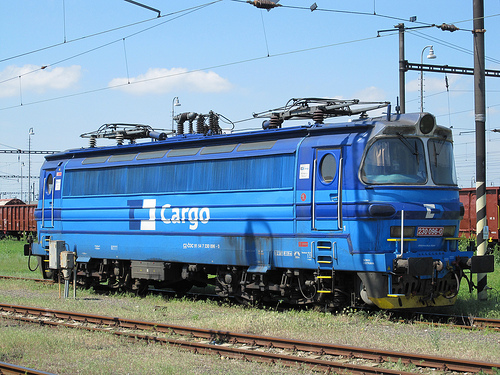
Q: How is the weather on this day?
A: It is clear.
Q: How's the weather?
A: It is clear.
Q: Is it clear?
A: Yes, it is clear.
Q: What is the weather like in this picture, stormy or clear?
A: It is clear.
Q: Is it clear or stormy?
A: It is clear.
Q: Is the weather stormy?
A: No, it is clear.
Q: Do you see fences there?
A: No, there are no fences.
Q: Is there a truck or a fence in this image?
A: No, there are no fences or trucks.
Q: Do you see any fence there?
A: No, there are no fences.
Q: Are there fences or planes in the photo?
A: No, there are no fences or planes.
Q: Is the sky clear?
A: Yes, the sky is clear.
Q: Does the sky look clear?
A: Yes, the sky is clear.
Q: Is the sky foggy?
A: No, the sky is clear.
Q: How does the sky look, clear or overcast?
A: The sky is clear.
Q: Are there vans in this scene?
A: No, there are no vans.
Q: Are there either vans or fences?
A: No, there are no vans or fences.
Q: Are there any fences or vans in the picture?
A: No, there are no vans or fences.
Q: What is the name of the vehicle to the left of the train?
A: The vehicle is a car.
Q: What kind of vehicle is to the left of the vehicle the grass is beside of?
A: The vehicle is a car.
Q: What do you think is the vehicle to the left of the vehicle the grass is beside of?
A: The vehicle is a car.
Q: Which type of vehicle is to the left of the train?
A: The vehicle is a car.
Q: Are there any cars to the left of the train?
A: Yes, there is a car to the left of the train.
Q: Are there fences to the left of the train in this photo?
A: No, there is a car to the left of the train.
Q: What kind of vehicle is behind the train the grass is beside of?
A: The vehicle is a car.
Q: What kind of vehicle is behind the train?
A: The vehicle is a car.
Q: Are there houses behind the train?
A: No, there is a car behind the train.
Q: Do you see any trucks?
A: No, there are no trucks.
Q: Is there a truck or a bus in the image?
A: No, there are no trucks or buses.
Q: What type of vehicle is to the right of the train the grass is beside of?
A: The vehicle is a car.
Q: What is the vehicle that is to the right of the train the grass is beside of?
A: The vehicle is a car.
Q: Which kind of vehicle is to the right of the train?
A: The vehicle is a car.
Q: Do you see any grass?
A: Yes, there is grass.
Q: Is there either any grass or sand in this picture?
A: Yes, there is grass.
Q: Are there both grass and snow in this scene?
A: No, there is grass but no snow.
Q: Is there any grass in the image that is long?
A: Yes, there is long grass.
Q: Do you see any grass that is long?
A: Yes, there is grass that is long.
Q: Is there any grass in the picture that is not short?
A: Yes, there is long grass.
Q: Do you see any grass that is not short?
A: Yes, there is long grass.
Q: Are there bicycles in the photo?
A: No, there are no bicycles.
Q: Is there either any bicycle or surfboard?
A: No, there are no bicycles or surfboards.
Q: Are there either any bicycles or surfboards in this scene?
A: No, there are no bicycles or surfboards.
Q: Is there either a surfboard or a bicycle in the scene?
A: No, there are no bicycles or surfboards.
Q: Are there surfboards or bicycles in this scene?
A: No, there are no bicycles or surfboards.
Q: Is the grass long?
A: Yes, the grass is long.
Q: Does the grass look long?
A: Yes, the grass is long.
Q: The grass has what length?
A: The grass is long.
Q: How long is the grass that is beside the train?
A: The grass is long.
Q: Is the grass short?
A: No, the grass is long.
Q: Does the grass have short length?
A: No, the grass is long.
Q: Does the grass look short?
A: No, the grass is long.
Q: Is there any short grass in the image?
A: No, there is grass but it is long.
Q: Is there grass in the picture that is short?
A: No, there is grass but it is long.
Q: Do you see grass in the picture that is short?
A: No, there is grass but it is long.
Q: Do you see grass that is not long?
A: No, there is grass but it is long.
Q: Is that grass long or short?
A: The grass is long.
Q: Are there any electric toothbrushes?
A: No, there are no electric toothbrushes.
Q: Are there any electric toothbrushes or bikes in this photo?
A: No, there are no electric toothbrushes or bikes.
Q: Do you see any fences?
A: No, there are no fences.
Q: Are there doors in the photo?
A: Yes, there is a door.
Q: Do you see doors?
A: Yes, there is a door.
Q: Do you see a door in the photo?
A: Yes, there is a door.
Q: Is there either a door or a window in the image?
A: Yes, there is a door.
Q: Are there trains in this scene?
A: Yes, there is a train.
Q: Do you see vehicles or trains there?
A: Yes, there is a train.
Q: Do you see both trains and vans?
A: No, there is a train but no vans.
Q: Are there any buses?
A: No, there are no buses.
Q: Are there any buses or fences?
A: No, there are no buses or fences.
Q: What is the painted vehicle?
A: The vehicle is a train.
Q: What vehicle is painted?
A: The vehicle is a train.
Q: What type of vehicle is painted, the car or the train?
A: The train is painted.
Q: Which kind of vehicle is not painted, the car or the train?
A: The car is not painted.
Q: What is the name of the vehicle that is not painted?
A: The vehicle is a car.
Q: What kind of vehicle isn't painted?
A: The vehicle is a car.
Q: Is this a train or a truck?
A: This is a train.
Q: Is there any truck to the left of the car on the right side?
A: No, there is a train to the left of the car.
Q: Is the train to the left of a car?
A: Yes, the train is to the left of a car.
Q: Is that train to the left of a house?
A: No, the train is to the left of a car.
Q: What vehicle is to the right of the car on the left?
A: The vehicle is a train.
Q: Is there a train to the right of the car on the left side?
A: Yes, there is a train to the right of the car.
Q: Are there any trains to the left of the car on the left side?
A: No, the train is to the right of the car.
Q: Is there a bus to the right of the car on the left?
A: No, there is a train to the right of the car.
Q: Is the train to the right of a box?
A: No, the train is to the right of the car.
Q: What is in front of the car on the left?
A: The train is in front of the car.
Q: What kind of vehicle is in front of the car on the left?
A: The vehicle is a train.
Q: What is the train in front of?
A: The train is in front of the car.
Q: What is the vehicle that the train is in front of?
A: The vehicle is a car.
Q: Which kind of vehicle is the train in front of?
A: The train is in front of the car.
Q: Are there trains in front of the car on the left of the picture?
A: Yes, there is a train in front of the car.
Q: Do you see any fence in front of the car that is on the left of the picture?
A: No, there is a train in front of the car.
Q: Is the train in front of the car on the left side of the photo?
A: Yes, the train is in front of the car.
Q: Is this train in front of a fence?
A: No, the train is in front of the car.